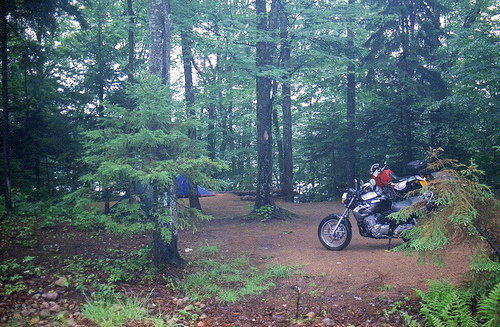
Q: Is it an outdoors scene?
A: Yes, it is outdoors.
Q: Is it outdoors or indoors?
A: It is outdoors.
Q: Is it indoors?
A: No, it is outdoors.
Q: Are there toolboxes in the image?
A: No, there are no toolboxes.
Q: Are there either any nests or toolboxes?
A: No, there are no toolboxes or nests.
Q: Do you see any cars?
A: No, there are no cars.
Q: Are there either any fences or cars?
A: No, there are no cars or fences.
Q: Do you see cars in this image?
A: No, there are no cars.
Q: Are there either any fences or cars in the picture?
A: No, there are no cars or fences.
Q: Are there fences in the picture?
A: No, there are no fences.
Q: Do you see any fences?
A: No, there are no fences.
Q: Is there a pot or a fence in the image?
A: No, there are no fences or pots.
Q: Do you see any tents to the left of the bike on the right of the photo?
A: Yes, there is a tent to the left of the bike.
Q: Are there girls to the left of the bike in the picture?
A: No, there is a tent to the left of the bike.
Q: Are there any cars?
A: No, there are no cars.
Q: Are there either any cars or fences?
A: No, there are no cars or fences.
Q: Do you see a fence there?
A: No, there are no fences.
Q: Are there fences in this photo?
A: No, there are no fences.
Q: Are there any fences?
A: No, there are no fences.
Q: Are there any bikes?
A: Yes, there is a bike.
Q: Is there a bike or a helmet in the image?
A: Yes, there is a bike.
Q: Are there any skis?
A: No, there are no skis.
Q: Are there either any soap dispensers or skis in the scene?
A: No, there are no skis or soap dispensers.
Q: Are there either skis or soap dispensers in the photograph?
A: No, there are no skis or soap dispensers.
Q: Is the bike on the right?
A: Yes, the bike is on the right of the image.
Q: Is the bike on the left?
A: No, the bike is on the right of the image.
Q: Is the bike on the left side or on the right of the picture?
A: The bike is on the right of the image.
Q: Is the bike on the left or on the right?
A: The bike is on the right of the image.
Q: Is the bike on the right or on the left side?
A: The bike is on the right of the image.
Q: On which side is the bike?
A: The bike is on the right of the image.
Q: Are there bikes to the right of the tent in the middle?
A: Yes, there is a bike to the right of the tent.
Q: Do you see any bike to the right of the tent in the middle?
A: Yes, there is a bike to the right of the tent.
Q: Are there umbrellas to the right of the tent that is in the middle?
A: No, there is a bike to the right of the tent.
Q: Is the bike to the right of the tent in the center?
A: Yes, the bike is to the right of the tent.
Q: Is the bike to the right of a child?
A: No, the bike is to the right of the tent.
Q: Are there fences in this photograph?
A: No, there are no fences.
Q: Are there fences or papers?
A: No, there are no fences or papers.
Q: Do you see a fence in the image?
A: No, there are no fences.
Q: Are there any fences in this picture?
A: No, there are no fences.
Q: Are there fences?
A: No, there are no fences.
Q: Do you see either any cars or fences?
A: No, there are no fences or cars.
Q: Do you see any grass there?
A: Yes, there is grass.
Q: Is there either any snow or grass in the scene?
A: Yes, there is grass.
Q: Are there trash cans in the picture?
A: No, there are no trash cans.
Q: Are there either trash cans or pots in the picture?
A: No, there are no trash cans or pots.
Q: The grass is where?
A: The grass is on the ground.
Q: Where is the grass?
A: The grass is on the ground.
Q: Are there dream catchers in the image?
A: No, there are no dream catchers.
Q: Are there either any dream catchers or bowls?
A: No, there are no dream catchers or bowls.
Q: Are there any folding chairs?
A: No, there are no folding chairs.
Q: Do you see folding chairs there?
A: No, there are no folding chairs.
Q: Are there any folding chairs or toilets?
A: No, there are no folding chairs or toilets.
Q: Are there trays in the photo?
A: No, there are no trays.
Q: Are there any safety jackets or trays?
A: No, there are no trays or safety jackets.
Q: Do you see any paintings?
A: No, there are no paintings.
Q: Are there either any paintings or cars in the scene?
A: No, there are no paintings or cars.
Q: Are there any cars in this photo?
A: No, there are no cars.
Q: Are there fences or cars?
A: No, there are no cars or fences.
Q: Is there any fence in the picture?
A: No, there are no fences.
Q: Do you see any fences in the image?
A: No, there are no fences.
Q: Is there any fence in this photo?
A: No, there are no fences.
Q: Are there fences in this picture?
A: No, there are no fences.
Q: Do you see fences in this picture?
A: No, there are no fences.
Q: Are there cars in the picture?
A: No, there are no cars.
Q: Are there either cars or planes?
A: No, there are no cars or planes.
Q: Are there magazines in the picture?
A: No, there are no magazines.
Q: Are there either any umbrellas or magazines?
A: No, there are no magazines or umbrellas.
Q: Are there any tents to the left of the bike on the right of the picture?
A: Yes, there is a tent to the left of the bike.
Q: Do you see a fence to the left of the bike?
A: No, there is a tent to the left of the bike.